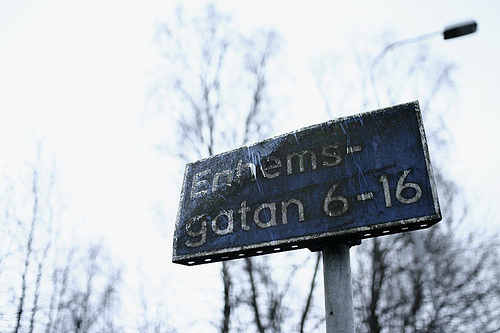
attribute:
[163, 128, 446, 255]
sign — blue, rusty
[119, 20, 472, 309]
tree — black, tall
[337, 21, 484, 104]
light — silver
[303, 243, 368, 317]
pole — grey, white